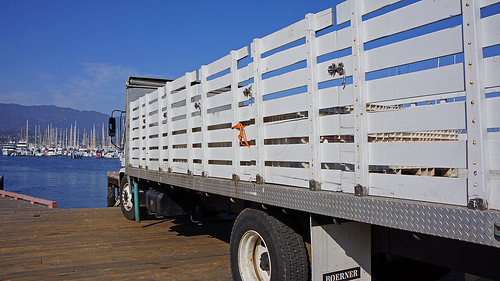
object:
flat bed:
[124, 0, 500, 242]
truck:
[105, 0, 500, 281]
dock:
[3, 137, 133, 237]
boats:
[104, 123, 118, 159]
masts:
[26, 119, 29, 140]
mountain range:
[0, 102, 112, 129]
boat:
[44, 122, 61, 156]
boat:
[82, 127, 88, 156]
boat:
[19, 118, 28, 156]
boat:
[70, 126, 82, 159]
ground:
[206, 263, 223, 281]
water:
[40, 179, 50, 186]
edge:
[245, 207, 275, 239]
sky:
[1, 1, 231, 78]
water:
[5, 159, 14, 165]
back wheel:
[229, 206, 310, 281]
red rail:
[0, 189, 58, 205]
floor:
[0, 197, 109, 280]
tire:
[118, 172, 143, 220]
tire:
[229, 207, 310, 281]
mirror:
[108, 117, 115, 137]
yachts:
[16, 125, 27, 147]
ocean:
[1, 158, 107, 206]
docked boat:
[35, 124, 43, 157]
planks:
[126, 58, 500, 139]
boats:
[1, 135, 17, 156]